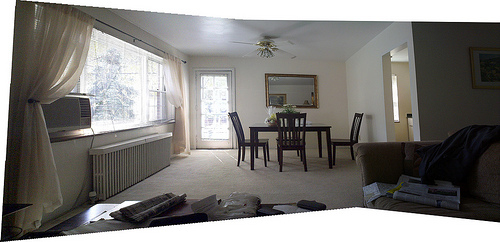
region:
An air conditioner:
[30, 85, 101, 140]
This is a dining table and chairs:
[225, 101, 366, 177]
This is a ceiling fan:
[227, 30, 305, 67]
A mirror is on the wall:
[258, 66, 329, 111]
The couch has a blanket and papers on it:
[350, 120, 496, 211]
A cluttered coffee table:
[62, 190, 319, 225]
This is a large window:
[92, 27, 179, 127]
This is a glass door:
[190, 62, 241, 154]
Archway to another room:
[372, 45, 427, 145]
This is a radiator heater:
[86, 132, 190, 197]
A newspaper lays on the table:
[106, 190, 196, 223]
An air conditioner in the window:
[43, 85, 98, 140]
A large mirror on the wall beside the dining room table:
[260, 66, 326, 113]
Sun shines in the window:
[100, 57, 190, 123]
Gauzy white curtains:
[150, 46, 215, 141]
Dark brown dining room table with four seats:
[219, 101, 384, 170]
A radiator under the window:
[86, 123, 178, 208]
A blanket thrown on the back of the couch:
[413, 115, 497, 185]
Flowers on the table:
[276, 101, 304, 127]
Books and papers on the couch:
[352, 153, 481, 214]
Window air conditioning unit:
[39, 98, 93, 133]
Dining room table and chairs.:
[227, 112, 365, 164]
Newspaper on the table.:
[118, 195, 187, 222]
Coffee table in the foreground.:
[50, 198, 303, 240]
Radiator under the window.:
[90, 137, 187, 194]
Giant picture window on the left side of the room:
[31, 12, 186, 126]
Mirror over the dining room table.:
[266, 72, 320, 105]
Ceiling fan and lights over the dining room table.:
[238, 28, 300, 60]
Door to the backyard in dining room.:
[193, 67, 238, 147]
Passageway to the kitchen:
[378, 50, 423, 164]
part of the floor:
[261, 165, 292, 186]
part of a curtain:
[18, 139, 56, 172]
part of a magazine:
[426, 181, 454, 211]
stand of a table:
[241, 134, 253, 179]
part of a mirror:
[283, 77, 320, 117]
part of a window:
[91, 72, 138, 104]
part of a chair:
[266, 103, 306, 154]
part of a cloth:
[440, 120, 475, 159]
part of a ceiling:
[322, 26, 355, 71]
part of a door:
[202, 107, 224, 139]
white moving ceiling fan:
[233, 23, 315, 68]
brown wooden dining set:
[211, 95, 370, 177]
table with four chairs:
[228, 97, 355, 177]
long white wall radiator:
[59, 113, 184, 195]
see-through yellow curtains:
[14, 0, 100, 240]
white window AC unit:
[28, 87, 100, 131]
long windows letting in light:
[28, 5, 203, 215]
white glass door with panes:
[189, 68, 239, 152]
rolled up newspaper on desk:
[103, 172, 196, 240]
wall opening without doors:
[372, 46, 416, 139]